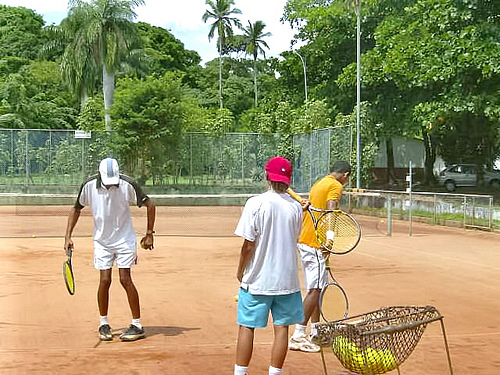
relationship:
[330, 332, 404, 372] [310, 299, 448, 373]
tennis balls in basket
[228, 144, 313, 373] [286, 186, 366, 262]
boy wears tennis racket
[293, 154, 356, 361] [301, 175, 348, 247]
boy wears shirt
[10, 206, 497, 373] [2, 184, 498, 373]
dirt on tennis court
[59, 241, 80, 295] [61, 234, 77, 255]
racket on hand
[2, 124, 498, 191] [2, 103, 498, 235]
fence around perimeter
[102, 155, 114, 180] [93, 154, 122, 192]
stripe on cap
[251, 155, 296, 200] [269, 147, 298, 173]
wearing a red cap backwards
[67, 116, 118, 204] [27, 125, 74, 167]
sign hanging on fence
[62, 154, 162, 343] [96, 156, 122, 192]
man man wearing a cap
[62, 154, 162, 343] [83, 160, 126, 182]
man mans hat gray and white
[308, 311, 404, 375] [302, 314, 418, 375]
these are ten balls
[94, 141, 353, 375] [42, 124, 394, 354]
people people playing tennis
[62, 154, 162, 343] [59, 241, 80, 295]
man with ten racket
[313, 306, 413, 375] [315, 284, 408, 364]
tennis balls in a basket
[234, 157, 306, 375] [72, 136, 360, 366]
people standing on a ten court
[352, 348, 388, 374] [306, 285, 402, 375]
tennis balls balls in a basket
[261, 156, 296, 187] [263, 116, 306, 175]
cap on persons head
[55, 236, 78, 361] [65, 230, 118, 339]
tennis racket in a hand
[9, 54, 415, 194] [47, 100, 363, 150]
leaves on many trees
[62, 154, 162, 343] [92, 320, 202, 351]
man has shadow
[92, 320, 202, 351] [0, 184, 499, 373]
shadow on tennis court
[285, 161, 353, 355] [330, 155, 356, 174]
boy has hair